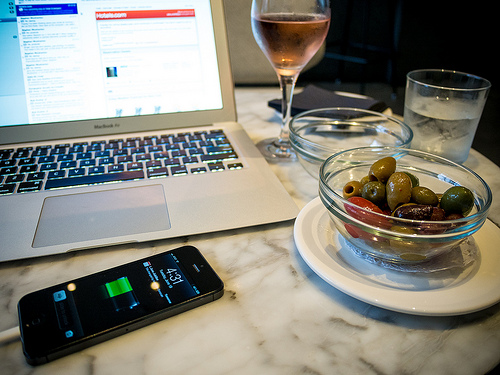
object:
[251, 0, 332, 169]
glass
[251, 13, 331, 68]
wine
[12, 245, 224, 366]
iphone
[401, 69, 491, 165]
glass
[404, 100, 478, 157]
ice water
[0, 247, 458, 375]
table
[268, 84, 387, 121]
napkins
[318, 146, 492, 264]
bowl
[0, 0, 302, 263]
laptop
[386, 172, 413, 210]
olives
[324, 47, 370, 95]
chair arms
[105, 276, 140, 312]
battery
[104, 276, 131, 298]
green bar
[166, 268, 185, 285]
time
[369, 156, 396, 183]
fruit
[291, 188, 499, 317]
dish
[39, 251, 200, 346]
screen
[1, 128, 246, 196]
keyboard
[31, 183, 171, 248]
touchpad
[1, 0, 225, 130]
screen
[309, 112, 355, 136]
glass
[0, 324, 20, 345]
battery cable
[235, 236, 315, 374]
counter